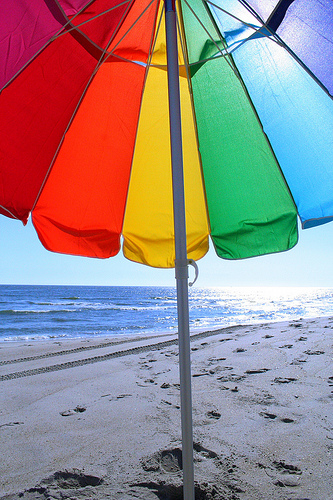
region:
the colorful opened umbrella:
[0, 0, 332, 499]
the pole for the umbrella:
[163, 0, 194, 498]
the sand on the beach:
[0, 316, 332, 499]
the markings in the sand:
[0, 317, 332, 498]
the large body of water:
[0, 284, 332, 343]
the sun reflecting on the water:
[156, 280, 332, 330]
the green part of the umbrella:
[179, 0, 298, 260]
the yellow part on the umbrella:
[122, 0, 209, 267]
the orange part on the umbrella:
[30, 0, 160, 259]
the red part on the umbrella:
[0, 0, 137, 225]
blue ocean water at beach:
[20, 278, 171, 341]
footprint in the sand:
[227, 343, 249, 357]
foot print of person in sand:
[50, 394, 90, 418]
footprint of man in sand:
[271, 371, 296, 391]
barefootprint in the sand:
[258, 451, 297, 487]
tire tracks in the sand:
[4, 354, 106, 391]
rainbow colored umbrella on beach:
[14, 10, 323, 276]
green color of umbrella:
[213, 31, 221, 253]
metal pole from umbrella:
[169, 217, 198, 494]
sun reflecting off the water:
[227, 283, 321, 311]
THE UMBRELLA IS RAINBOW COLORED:
[0, 1, 332, 275]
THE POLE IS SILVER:
[157, 1, 200, 499]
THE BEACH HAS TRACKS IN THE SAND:
[2, 311, 332, 498]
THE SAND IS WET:
[2, 316, 332, 499]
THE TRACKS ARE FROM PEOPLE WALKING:
[8, 314, 331, 499]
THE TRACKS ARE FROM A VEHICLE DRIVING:
[0, 322, 257, 384]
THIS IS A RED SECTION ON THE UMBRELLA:
[0, 0, 137, 225]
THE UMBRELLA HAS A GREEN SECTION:
[179, 0, 302, 262]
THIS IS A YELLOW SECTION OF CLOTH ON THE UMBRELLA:
[121, 0, 209, 273]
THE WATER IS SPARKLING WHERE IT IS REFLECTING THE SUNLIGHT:
[152, 283, 331, 327]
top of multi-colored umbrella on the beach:
[3, 1, 329, 269]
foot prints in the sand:
[13, 437, 223, 495]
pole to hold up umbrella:
[163, 2, 196, 495]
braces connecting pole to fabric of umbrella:
[0, 2, 157, 233]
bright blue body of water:
[1, 285, 331, 346]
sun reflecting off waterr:
[201, 287, 331, 320]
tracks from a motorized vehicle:
[0, 325, 234, 384]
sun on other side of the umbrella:
[215, 2, 317, 80]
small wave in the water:
[2, 298, 167, 315]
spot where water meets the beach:
[0, 310, 332, 351]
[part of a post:
[185, 454, 199, 481]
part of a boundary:
[198, 440, 222, 474]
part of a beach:
[249, 419, 276, 458]